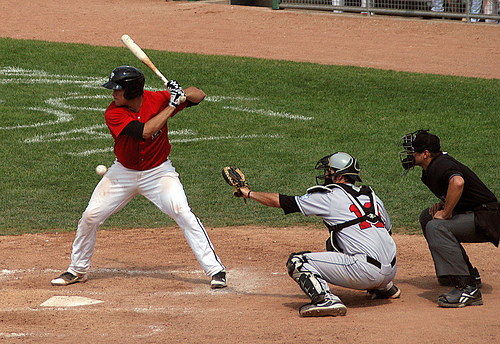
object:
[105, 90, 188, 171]
shirt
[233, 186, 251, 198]
hand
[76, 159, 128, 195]
baseball flying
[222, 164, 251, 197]
baseball glove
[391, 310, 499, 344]
infield clay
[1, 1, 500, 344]
infield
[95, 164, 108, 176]
ball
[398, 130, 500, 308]
man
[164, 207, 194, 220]
knee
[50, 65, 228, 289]
batter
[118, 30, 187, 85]
bat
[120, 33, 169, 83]
baseball bat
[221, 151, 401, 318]
catcher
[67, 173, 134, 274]
legs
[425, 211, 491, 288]
legs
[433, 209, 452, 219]
hands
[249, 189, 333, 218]
arm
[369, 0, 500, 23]
dugout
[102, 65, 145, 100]
helmet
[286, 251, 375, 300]
leg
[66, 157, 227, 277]
trouser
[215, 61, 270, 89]
grass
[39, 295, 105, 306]
home plate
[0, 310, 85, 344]
dirt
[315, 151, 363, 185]
face guard